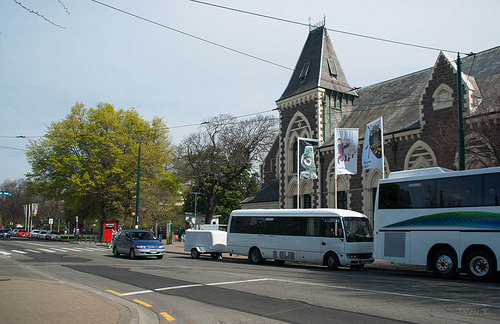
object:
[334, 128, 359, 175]
banners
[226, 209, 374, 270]
bus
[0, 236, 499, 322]
ground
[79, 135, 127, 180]
leaves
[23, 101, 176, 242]
green tree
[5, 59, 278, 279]
distance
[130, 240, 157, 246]
blue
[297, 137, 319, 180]
poster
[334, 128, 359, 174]
poster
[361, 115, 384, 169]
poster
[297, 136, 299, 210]
pole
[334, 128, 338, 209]
pole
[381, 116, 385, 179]
pole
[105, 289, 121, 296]
dashes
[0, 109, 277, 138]
wire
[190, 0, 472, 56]
phone wires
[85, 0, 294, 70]
phone wires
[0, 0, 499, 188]
sky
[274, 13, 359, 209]
churchtower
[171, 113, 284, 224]
tree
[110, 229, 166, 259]
car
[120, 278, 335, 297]
white line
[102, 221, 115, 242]
booth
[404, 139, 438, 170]
arch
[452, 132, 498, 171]
arch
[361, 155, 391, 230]
arch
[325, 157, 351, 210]
arch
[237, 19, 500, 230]
facade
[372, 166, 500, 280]
bus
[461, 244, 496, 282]
black wheel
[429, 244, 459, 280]
black wheel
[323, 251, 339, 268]
black wheel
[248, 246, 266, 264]
black wheel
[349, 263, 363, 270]
black wheel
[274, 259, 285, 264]
black wheel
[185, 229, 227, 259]
trailer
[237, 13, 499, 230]
building